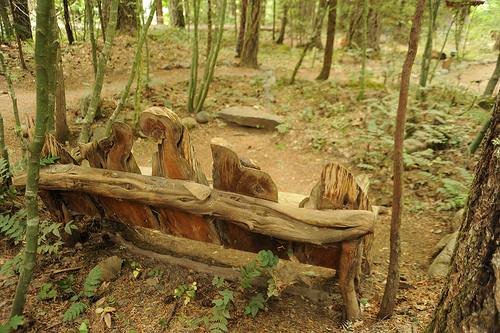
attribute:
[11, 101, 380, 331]
bench — empty, wooden, restful, wood, old, reclaimed wood, man-made, custom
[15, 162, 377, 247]
log — brown, wooden, long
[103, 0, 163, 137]
stem — weak, thin, green, tall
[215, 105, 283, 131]
rock — large, big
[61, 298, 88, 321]
leaves — green, small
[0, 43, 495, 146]
trail — small, leading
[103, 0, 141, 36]
tree — distant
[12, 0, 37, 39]
tree — distant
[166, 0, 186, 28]
tree — distant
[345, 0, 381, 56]
tree — distant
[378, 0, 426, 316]
trunk — tall, skinny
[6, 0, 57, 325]
trunk — skinny, green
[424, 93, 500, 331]
trunk — tree, bark, big, tall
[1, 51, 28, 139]
root — green, tall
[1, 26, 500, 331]
ground — weedy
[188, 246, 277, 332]
plant — growing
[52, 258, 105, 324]
plant — growing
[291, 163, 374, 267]
plank — wooden, small